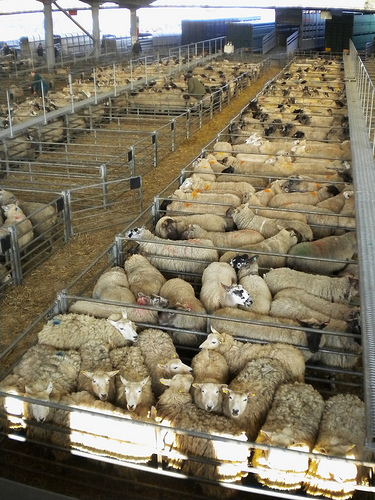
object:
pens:
[98, 150, 136, 212]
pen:
[99, 251, 362, 341]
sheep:
[228, 246, 272, 318]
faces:
[226, 283, 253, 307]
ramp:
[263, 35, 296, 56]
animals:
[197, 256, 255, 322]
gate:
[60, 169, 147, 241]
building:
[319, 5, 373, 57]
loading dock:
[151, 0, 375, 51]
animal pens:
[184, 100, 204, 141]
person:
[31, 67, 52, 105]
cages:
[59, 232, 363, 405]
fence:
[65, 173, 148, 240]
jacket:
[30, 74, 53, 92]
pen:
[0, 69, 76, 140]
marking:
[189, 191, 200, 201]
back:
[180, 189, 237, 205]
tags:
[192, 194, 202, 202]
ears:
[188, 184, 197, 193]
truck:
[271, 11, 328, 50]